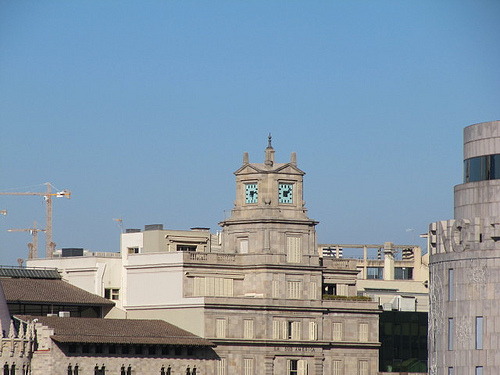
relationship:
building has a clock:
[124, 134, 378, 373] [241, 180, 262, 205]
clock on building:
[241, 180, 262, 205] [124, 134, 378, 373]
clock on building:
[275, 179, 296, 206] [124, 134, 378, 373]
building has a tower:
[124, 134, 378, 373] [233, 130, 307, 217]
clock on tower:
[241, 180, 262, 205] [233, 130, 307, 217]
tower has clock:
[233, 130, 307, 217] [244, 182, 259, 204]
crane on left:
[1, 177, 74, 258] [0, 1, 7, 370]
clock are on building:
[244, 182, 259, 204] [124, 134, 378, 373]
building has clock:
[124, 134, 378, 373] [244, 182, 259, 204]